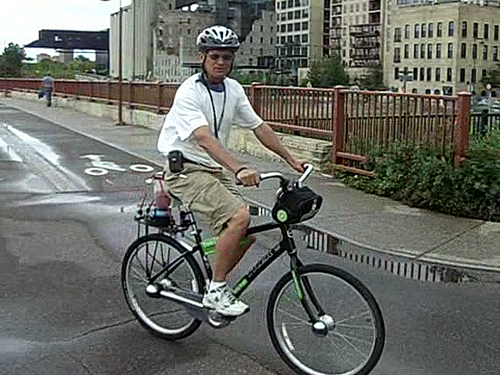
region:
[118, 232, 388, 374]
Two bike wheels with tires and spokes.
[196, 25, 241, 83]
Man wearing a helmet.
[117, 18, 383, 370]
A man is riding a bike.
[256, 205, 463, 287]
The curb has vertical lines.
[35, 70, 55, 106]
A man is walking holding a bag.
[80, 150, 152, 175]
Bike lane marking on ground.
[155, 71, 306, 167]
A person wearing a white shirt.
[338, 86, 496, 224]
Green bushes by a section of fence.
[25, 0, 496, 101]
City buildings in background.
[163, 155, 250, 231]
A man is wearing tan shorts.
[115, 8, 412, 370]
a person on a bike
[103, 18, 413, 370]
A man on a bike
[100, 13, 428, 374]
A person on a bicycle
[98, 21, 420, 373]
a man on a bicycle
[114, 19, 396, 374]
A person riding a bike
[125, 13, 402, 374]
a man riding a bicycle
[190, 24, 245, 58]
A helmet on a man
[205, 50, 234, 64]
Glasses on a man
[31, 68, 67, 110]
A person walking on the sidewalk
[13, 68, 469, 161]
A fence near the sidewalk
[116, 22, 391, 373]
A MAN RIDING A BIKE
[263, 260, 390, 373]
A FRONT BIKE TIRE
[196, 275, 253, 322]
A WHITE SNEAKER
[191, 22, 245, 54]
A BICYCLE HELMET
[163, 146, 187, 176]
A BLACK CELL PHONE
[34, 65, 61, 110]
A PERSON WALKING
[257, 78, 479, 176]
A RED METAL FENCE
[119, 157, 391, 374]
A BLACK AND GREEN BIKE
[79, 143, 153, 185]
WHITE MARKINGS ON THE STREET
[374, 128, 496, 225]
BUSHES NEAR THE FENCE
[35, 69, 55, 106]
Person walking on the sidewalk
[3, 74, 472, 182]
Metal fence along the sidewalk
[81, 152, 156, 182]
Bicycle sign on the ground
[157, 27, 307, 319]
Man riding a bicycle on the street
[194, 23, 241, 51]
Helmet on the man's head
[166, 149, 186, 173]
Cellphone hanging on the man's belt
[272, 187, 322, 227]
Bag on the front of the bike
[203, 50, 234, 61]
Sunglasses on the man's face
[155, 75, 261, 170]
White shirt on the man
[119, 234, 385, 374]
Wheels of the bicycle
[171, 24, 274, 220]
man with white and silver helmet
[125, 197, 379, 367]
bottom view of bicycle with person on it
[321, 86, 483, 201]
view of brown fence in green plants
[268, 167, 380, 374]
front view of bicycle with bag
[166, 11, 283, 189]
man wearing white shirt with cell phone holder on side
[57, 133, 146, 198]
biking right of way sign on concrete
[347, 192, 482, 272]
puddle in corner off sidewalk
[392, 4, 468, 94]
front view of concrete building with windows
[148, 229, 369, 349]
green and black bike on pavement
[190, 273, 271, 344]
white sneaker on bike peddle